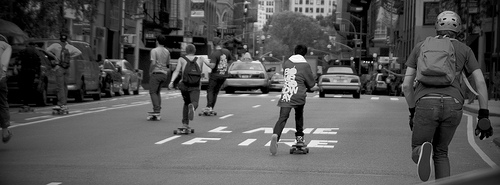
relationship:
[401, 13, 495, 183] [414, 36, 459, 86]
guy has on backpack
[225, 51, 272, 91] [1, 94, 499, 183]
taxi driving on road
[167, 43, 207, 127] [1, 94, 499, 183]
girl skateboarding on road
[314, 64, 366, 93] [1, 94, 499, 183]
car driving on road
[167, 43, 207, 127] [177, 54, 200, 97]
girl wearing backpack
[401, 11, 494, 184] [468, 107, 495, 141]
guy wearing gloves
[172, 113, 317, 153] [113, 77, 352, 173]
fire lane marked in street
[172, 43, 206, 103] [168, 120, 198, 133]
girl riding skateboard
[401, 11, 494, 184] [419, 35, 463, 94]
guy wearing backpack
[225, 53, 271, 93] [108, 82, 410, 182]
taxi in street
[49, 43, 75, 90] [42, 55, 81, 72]
man has hands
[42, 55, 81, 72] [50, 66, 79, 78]
hands are on hips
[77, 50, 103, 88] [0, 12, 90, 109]
pickup truck parked on side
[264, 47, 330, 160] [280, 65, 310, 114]
man wearing jacket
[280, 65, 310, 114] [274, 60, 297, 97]
jacket has writing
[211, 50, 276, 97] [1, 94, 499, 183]
cab on road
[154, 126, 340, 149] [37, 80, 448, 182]
fire lane on street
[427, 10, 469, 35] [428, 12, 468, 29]
helmet on head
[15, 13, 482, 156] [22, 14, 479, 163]
view of city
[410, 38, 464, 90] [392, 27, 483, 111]
backpack on back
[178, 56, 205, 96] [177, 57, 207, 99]
backpack on back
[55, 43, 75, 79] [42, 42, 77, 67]
backpack on back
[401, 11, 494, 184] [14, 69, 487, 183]
guy in street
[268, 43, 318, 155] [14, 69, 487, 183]
man in street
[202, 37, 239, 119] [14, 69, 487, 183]
person in street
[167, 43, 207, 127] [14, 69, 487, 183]
girl in street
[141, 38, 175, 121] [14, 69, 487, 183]
person in street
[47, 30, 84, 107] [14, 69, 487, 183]
man in street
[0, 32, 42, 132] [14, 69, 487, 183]
person in street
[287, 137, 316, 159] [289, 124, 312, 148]
roller skates on foot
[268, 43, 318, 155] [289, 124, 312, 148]
man has foot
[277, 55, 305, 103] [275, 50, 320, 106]
symbol on back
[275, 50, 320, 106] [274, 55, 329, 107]
back belongs to jacket